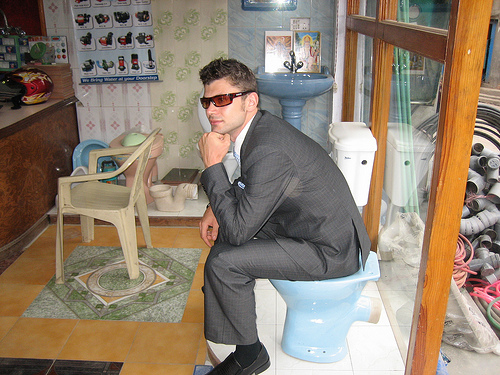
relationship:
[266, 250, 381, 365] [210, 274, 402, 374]
toliet over tile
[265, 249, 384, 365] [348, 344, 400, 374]
seat over tile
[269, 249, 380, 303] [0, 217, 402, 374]
toilet seat on tile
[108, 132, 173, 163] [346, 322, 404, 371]
toilet seat on tile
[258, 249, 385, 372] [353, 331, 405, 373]
seat on tile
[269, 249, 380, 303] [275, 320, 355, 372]
toilet seat on tile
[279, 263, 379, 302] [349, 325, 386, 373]
toilet seat on tile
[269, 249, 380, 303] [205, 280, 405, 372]
toilet seat on tile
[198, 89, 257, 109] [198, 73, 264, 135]
glasses on face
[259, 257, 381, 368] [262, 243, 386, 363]
toilet with no seat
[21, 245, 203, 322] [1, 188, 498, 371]
design on floor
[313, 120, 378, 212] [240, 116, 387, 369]
back of toilet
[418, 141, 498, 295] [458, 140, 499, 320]
amount of plumbing pipes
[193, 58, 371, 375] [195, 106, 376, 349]
man with suit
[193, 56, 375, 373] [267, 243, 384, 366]
man on toilet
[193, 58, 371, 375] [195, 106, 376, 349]
man in suit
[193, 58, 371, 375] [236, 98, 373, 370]
man on toilet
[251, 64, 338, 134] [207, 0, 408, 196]
sink against wall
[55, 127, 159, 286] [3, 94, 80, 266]
chair in front of counter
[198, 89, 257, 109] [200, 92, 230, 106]
glasses over eyes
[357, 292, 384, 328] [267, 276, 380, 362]
part of blue toilet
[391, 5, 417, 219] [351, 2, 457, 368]
curtain reflected in glass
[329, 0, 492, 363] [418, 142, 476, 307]
window with trim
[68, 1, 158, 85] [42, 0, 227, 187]
poster on wall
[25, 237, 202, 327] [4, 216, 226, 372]
tile inlay on floor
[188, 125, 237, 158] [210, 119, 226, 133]
hand under chin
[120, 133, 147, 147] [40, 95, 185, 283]
ball on chair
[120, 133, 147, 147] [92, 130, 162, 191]
ball on chair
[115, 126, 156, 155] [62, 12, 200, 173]
ball by wall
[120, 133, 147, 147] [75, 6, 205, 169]
ball by wall